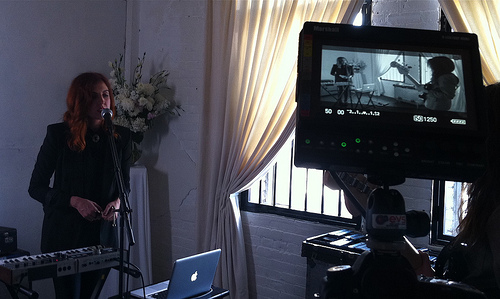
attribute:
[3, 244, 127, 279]
keyboard — electronic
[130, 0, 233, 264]
wall — white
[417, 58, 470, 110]
woman — black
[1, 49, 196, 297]
woman — singer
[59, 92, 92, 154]
hair — brown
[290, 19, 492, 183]
camera — rectangular, black, on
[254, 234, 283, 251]
brick — white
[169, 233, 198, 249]
brick — white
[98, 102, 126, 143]
microphone — black, gray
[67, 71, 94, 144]
hair — long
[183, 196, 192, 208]
brick — white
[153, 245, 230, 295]
computer — laptop, silver, flat, small, rectangular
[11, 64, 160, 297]
woman — black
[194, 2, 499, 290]
curtain — beige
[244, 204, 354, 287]
wall — white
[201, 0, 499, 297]
curtains — floor length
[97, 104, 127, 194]
microphone — black, silver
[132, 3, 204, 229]
brick — white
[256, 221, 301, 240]
brick — white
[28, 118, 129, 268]
jacket — long